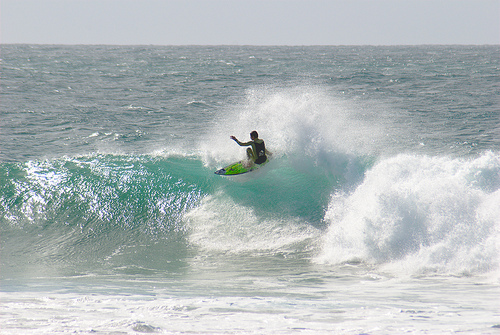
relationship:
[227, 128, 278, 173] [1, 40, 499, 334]
person in ocean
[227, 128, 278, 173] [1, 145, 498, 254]
person riding wave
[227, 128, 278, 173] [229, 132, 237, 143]
person has hand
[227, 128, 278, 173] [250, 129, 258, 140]
person has hair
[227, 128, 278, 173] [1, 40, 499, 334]
person on ocean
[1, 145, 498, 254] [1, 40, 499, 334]
wave in ocean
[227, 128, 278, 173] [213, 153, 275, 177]
person on surfboard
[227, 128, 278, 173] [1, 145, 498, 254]
person on wave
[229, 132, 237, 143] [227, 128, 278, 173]
hand of person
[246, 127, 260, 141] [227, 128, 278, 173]
head of person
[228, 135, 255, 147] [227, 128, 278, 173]
arm of person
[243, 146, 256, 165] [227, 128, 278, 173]
leg of person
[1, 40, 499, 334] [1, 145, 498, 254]
ocean behind wave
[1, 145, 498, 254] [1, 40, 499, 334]
wave of ocean